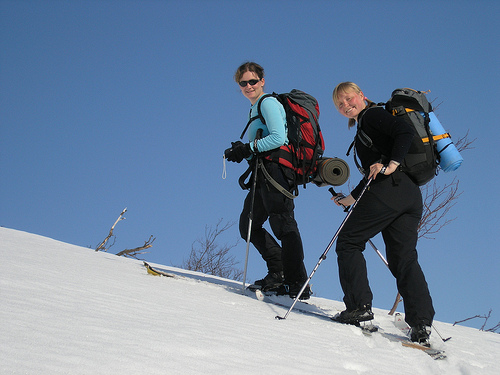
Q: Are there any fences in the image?
A: No, there are no fences.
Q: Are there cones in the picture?
A: No, there are no cones.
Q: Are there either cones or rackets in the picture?
A: No, there are no cones or rackets.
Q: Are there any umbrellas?
A: No, there are no umbrellas.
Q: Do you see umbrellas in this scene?
A: No, there are no umbrellas.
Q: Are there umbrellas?
A: No, there are no umbrellas.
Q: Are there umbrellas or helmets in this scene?
A: No, there are no umbrellas or helmets.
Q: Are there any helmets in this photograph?
A: No, there are no helmets.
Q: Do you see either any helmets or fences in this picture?
A: No, there are no helmets or fences.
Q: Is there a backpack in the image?
A: Yes, there is a backpack.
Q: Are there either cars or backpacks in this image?
A: Yes, there is a backpack.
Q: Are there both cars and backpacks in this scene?
A: No, there is a backpack but no cars.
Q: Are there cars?
A: No, there are no cars.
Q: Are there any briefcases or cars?
A: No, there are no cars or briefcases.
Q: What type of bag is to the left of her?
A: The bag is a backpack.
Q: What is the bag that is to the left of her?
A: The bag is a backpack.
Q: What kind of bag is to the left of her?
A: The bag is a backpack.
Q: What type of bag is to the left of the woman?
A: The bag is a backpack.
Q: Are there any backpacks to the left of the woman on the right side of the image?
A: Yes, there is a backpack to the left of the woman.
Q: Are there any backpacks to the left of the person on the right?
A: Yes, there is a backpack to the left of the woman.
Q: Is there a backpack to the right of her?
A: No, the backpack is to the left of the woman.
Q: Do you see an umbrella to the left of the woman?
A: No, there is a backpack to the left of the woman.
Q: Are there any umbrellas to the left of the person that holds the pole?
A: No, there is a backpack to the left of the woman.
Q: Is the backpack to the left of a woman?
A: Yes, the backpack is to the left of a woman.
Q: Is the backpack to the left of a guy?
A: No, the backpack is to the left of a woman.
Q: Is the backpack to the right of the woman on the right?
A: No, the backpack is to the left of the woman.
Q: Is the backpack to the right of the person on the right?
A: No, the backpack is to the left of the woman.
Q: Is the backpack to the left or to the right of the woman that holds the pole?
A: The backpack is to the left of the woman.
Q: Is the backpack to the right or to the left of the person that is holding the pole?
A: The backpack is to the left of the woman.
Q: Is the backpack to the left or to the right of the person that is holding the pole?
A: The backpack is to the left of the woman.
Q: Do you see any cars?
A: No, there are no cars.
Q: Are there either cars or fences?
A: No, there are no cars or fences.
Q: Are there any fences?
A: No, there are no fences.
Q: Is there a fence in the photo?
A: No, there are no fences.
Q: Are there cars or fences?
A: No, there are no fences or cars.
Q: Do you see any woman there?
A: Yes, there is a woman.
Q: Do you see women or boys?
A: Yes, there is a woman.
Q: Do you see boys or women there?
A: Yes, there is a woman.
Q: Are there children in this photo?
A: No, there are no children.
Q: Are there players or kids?
A: No, there are no kids or players.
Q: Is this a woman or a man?
A: This is a woman.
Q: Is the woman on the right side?
A: Yes, the woman is on the right of the image.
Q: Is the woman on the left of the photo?
A: No, the woman is on the right of the image.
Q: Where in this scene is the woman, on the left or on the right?
A: The woman is on the right of the image.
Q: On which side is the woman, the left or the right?
A: The woman is on the right of the image.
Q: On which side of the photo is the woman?
A: The woman is on the right of the image.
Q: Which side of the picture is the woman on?
A: The woman is on the right of the image.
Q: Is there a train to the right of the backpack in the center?
A: No, there is a woman to the right of the backpack.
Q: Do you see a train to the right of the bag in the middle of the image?
A: No, there is a woman to the right of the backpack.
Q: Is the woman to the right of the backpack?
A: Yes, the woman is to the right of the backpack.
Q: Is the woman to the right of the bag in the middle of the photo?
A: Yes, the woman is to the right of the backpack.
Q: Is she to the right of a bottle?
A: No, the woman is to the right of the backpack.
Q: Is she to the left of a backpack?
A: No, the woman is to the right of a backpack.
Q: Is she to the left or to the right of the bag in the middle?
A: The woman is to the right of the backpack.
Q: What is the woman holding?
A: The woman is holding the pole.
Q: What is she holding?
A: The woman is holding the pole.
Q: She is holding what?
A: The woman is holding the pole.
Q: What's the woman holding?
A: The woman is holding the pole.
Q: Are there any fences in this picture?
A: No, there are no fences.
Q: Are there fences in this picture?
A: No, there are no fences.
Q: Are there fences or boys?
A: No, there are no fences or boys.